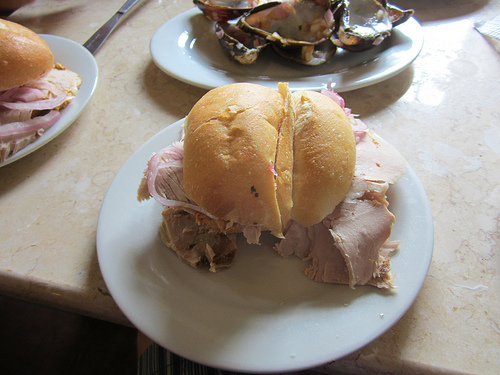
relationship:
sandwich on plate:
[140, 79, 401, 297] [92, 115, 437, 373]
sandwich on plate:
[0, 16, 80, 156] [3, 30, 99, 169]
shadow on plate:
[102, 238, 401, 360] [92, 115, 437, 373]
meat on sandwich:
[134, 81, 401, 296] [140, 79, 401, 297]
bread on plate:
[184, 80, 359, 240] [92, 115, 437, 373]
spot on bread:
[243, 183, 264, 199] [184, 80, 359, 240]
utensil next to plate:
[81, 0, 143, 54] [151, 3, 425, 90]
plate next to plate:
[3, 30, 99, 169] [151, 3, 425, 90]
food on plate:
[186, 0, 416, 68] [151, 3, 425, 90]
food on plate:
[140, 81, 398, 297] [92, 115, 437, 373]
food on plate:
[1, 17, 80, 160] [3, 30, 99, 169]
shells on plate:
[192, 12, 385, 68] [151, 3, 425, 90]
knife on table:
[81, 0, 153, 56] [0, 2, 499, 371]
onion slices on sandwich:
[4, 90, 69, 142] [0, 16, 80, 156]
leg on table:
[130, 324, 178, 373] [0, 2, 499, 371]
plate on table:
[92, 115, 437, 373] [0, 2, 499, 371]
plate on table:
[3, 30, 99, 169] [0, 2, 499, 371]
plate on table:
[151, 3, 425, 90] [0, 2, 499, 371]